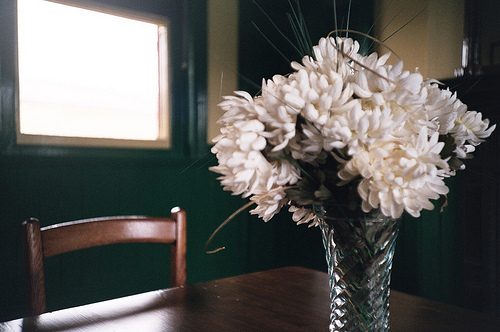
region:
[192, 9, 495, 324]
arrangement of white flowers inside vase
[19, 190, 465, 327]
chair pushed under edge of table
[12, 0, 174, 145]
bright light coming from screen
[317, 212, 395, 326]
ridged surface of glass vase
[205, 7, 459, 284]
dark corner in room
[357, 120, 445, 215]
curved white petals forming flower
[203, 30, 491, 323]
Flowers in a vase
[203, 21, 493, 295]
White flowers in a vase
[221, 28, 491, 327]
Flowers in a glass vase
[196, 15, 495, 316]
White flowers in a glass vase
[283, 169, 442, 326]
The vase has flowers in it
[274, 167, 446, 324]
The glass vase has flowers in it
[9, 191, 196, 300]
Top of a chair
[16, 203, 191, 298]
Top of a wooden chair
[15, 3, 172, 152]
Sunshine coming from a window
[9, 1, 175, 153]
Daylight coming from a window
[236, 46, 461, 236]
white flowers in vase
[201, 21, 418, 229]
brown fronds on flowers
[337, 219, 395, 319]
clear and glass vase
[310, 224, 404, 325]
vase on brown table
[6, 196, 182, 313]
brown chair near table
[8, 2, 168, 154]
white frame on window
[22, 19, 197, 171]
light shines through window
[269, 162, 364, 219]
green stems on flowers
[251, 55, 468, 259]
large bouquet of white flowers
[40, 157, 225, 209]
green wall behind chair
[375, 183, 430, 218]
flowers in a vase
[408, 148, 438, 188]
flowers in a vase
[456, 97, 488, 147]
flowers in a vase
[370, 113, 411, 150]
flower in a vase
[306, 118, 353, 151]
flowers in a vase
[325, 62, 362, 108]
flowers in a vase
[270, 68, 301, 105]
flowers in a vase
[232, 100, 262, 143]
flowers in a vase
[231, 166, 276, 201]
flowers in a vase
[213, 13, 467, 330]
vase full of flowers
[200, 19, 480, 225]
white flowers in the vase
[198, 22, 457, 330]
Vase on the table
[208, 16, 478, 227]
White flowers in the vase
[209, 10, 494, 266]
glass vase with white flowers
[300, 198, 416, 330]
vase on the table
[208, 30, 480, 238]
flowers in the vase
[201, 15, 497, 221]
flowers in the vase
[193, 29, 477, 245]
flowers in the vase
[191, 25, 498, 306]
flowers in the vase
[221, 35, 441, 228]
Flowers in a vase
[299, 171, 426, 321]
Glass vase on the table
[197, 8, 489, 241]
flowers in a glass vase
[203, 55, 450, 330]
glass vase on the table